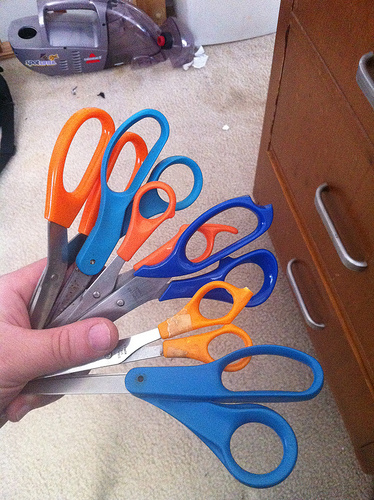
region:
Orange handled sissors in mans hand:
[42, 97, 88, 248]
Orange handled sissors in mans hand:
[133, 173, 164, 251]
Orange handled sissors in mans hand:
[121, 315, 255, 349]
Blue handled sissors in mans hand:
[112, 361, 304, 490]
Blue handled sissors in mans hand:
[139, 254, 296, 305]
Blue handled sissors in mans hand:
[112, 108, 193, 208]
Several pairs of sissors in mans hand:
[17, 94, 306, 477]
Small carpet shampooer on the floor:
[3, 5, 228, 80]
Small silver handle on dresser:
[278, 248, 326, 342]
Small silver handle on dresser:
[301, 174, 370, 287]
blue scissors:
[153, 373, 210, 410]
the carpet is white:
[79, 437, 148, 477]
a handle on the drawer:
[287, 283, 316, 315]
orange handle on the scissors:
[171, 318, 205, 346]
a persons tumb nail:
[88, 328, 109, 347]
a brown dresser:
[282, 143, 321, 172]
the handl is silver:
[318, 207, 356, 252]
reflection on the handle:
[266, 273, 276, 284]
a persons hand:
[0, 288, 48, 370]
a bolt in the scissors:
[115, 298, 129, 307]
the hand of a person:
[0, 257, 119, 426]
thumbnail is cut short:
[88, 322, 109, 349]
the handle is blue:
[125, 344, 322, 487]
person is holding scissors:
[0, 107, 325, 487]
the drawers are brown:
[253, 1, 372, 472]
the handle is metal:
[287, 258, 322, 328]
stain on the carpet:
[197, 69, 264, 114]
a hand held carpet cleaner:
[9, 0, 191, 73]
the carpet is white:
[0, 33, 372, 497]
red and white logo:
[82, 53, 102, 63]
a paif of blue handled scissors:
[24, 343, 333, 487]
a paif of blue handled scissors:
[40, 102, 201, 314]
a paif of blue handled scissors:
[57, 192, 274, 345]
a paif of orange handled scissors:
[49, 105, 146, 324]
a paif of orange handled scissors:
[77, 182, 236, 323]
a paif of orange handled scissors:
[37, 283, 249, 383]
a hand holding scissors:
[2, 255, 116, 419]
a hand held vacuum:
[3, 1, 210, 79]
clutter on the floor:
[182, 46, 209, 72]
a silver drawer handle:
[285, 256, 329, 332]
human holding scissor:
[3, 100, 325, 495]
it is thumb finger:
[27, 312, 120, 365]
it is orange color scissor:
[38, 101, 96, 229]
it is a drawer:
[254, 2, 372, 393]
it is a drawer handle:
[311, 180, 368, 276]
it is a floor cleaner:
[3, 0, 198, 85]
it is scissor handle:
[215, 341, 326, 498]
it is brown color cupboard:
[251, 0, 371, 468]